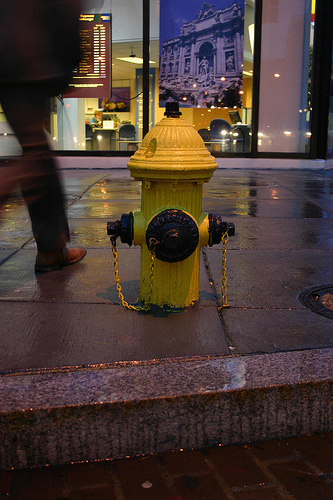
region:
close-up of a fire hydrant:
[6, 11, 318, 365]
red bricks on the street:
[155, 449, 308, 494]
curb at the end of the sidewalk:
[40, 370, 188, 444]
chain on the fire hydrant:
[104, 233, 159, 312]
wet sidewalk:
[218, 169, 317, 208]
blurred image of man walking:
[1, 48, 87, 274]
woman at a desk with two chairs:
[83, 101, 129, 144]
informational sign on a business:
[79, 8, 109, 97]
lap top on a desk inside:
[224, 107, 245, 123]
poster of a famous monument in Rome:
[160, 3, 240, 104]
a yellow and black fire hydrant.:
[102, 98, 241, 316]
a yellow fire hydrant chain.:
[215, 229, 235, 312]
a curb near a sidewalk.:
[0, 345, 331, 476]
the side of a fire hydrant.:
[143, 203, 206, 267]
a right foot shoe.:
[31, 237, 87, 278]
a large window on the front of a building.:
[138, 0, 264, 154]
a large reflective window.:
[256, 0, 315, 155]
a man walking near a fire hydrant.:
[0, 0, 102, 275]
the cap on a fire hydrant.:
[162, 95, 182, 123]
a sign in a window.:
[58, 9, 123, 101]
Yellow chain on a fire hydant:
[102, 228, 160, 315]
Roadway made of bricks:
[0, 427, 332, 499]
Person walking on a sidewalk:
[0, 0, 94, 277]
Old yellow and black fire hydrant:
[105, 96, 237, 312]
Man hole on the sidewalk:
[298, 280, 332, 321]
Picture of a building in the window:
[157, 1, 245, 108]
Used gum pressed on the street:
[136, 478, 155, 490]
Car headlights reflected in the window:
[217, 127, 314, 144]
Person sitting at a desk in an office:
[89, 108, 107, 131]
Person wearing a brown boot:
[0, 0, 106, 274]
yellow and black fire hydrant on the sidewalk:
[104, 98, 231, 313]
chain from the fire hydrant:
[213, 228, 231, 313]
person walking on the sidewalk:
[0, 4, 96, 269]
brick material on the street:
[0, 431, 329, 499]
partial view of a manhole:
[301, 284, 331, 323]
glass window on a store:
[54, 4, 259, 155]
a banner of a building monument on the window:
[154, 0, 242, 104]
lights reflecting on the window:
[207, 122, 321, 151]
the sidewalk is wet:
[2, 159, 326, 256]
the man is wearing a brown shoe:
[30, 239, 87, 272]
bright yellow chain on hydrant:
[220, 235, 231, 310]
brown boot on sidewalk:
[34, 242, 88, 277]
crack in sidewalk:
[202, 253, 217, 293]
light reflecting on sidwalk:
[236, 189, 248, 217]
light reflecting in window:
[282, 128, 292, 137]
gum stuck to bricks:
[138, 475, 155, 493]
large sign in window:
[161, 1, 237, 108]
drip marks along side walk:
[109, 436, 160, 452]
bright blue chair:
[205, 114, 228, 138]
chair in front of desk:
[114, 126, 142, 151]